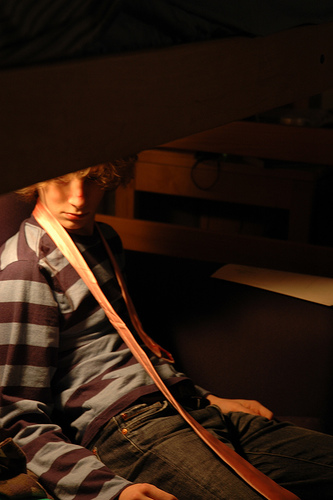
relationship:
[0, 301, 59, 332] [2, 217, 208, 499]
black stripe on shirt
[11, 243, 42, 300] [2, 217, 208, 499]
black stripe of shirt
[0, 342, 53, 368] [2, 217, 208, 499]
black stripe on shirt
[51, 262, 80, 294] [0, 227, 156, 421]
black stripe on shirt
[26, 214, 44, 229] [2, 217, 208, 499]
stripe on shirt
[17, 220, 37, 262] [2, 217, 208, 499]
stripe on shirt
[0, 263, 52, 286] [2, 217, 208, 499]
black stripe on shirt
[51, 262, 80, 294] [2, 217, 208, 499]
black stripe on shirt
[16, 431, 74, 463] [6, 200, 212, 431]
stripe on shirt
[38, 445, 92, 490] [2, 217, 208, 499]
stripe on shirt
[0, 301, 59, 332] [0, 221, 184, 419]
black stripe on shirt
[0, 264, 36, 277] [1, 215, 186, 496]
black stripe on shirt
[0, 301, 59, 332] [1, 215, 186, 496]
black stripe on shirt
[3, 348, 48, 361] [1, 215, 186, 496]
black stripe on shirt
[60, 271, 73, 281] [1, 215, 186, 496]
black stripe on shirt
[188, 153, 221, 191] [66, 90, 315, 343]
black circle outside bed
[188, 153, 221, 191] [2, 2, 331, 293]
black circle outside bed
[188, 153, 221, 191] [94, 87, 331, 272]
black circle outside bed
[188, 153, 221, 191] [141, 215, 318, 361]
black circle outside bed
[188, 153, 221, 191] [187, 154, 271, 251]
black circle outside bed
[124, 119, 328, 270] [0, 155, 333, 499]
desk behind boy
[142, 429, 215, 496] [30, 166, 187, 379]
jeans of man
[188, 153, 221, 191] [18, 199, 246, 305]
black circle outside of bed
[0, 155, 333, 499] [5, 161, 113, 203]
boy has hair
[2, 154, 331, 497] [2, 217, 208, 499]
boy wearing shirt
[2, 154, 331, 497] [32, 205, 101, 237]
boy possesses neck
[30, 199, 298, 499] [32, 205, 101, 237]
tie around neck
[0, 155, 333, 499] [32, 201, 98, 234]
boy possesses neck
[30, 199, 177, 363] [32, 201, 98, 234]
tie around neck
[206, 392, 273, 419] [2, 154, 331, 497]
hand of boy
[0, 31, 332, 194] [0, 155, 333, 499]
plank above boy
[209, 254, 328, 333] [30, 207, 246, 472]
paper next to boy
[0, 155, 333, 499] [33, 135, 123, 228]
boy possesses head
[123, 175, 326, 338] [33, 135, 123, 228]
mattress over head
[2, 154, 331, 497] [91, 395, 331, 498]
boy wearing jeans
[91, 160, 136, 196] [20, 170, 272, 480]
hair on boy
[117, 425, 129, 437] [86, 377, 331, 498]
clasp on jeans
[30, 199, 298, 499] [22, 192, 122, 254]
tie around neck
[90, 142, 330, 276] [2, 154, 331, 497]
shelf behind boy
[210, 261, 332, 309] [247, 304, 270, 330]
paper on bed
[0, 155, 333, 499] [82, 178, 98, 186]
boy possesses eye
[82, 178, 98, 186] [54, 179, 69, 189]
eye possesses eye